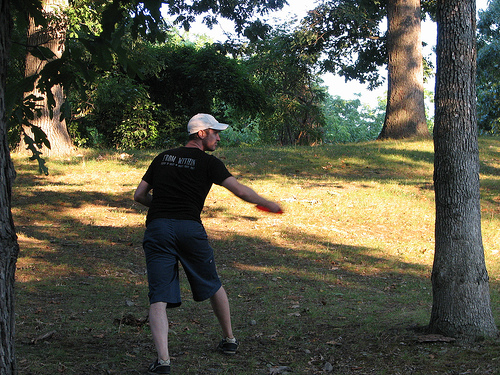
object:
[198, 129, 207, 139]
ear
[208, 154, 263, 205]
arm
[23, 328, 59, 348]
stick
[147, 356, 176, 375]
shoe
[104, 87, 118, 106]
leaf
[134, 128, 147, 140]
leaf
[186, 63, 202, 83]
leaf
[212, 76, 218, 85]
leaf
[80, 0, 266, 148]
tree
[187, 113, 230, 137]
cap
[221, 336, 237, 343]
socks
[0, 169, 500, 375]
shadow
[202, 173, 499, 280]
sunny area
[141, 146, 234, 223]
shirt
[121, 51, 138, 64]
leaf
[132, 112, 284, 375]
man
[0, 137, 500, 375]
leaves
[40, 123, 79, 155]
sunlight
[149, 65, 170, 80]
leaf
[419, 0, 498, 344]
tree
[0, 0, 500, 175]
green leaf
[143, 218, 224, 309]
grey shorts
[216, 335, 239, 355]
shoe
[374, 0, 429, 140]
tree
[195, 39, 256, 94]
leaf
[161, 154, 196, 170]
print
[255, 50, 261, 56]
leaf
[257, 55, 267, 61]
leaf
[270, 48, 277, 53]
leaf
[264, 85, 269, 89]
leaf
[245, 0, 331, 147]
tree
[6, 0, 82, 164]
tree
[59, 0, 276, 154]
shrub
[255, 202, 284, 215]
frisbee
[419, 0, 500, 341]
tree trunk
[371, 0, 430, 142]
tree trunk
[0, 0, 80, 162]
tree trunk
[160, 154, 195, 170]
writing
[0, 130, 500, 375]
grass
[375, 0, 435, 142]
shadow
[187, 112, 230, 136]
hat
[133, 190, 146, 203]
elbow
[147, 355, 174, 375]
foot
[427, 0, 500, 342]
bark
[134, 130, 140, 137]
leaf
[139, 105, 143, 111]
leaf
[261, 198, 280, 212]
hand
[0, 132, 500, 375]
ground